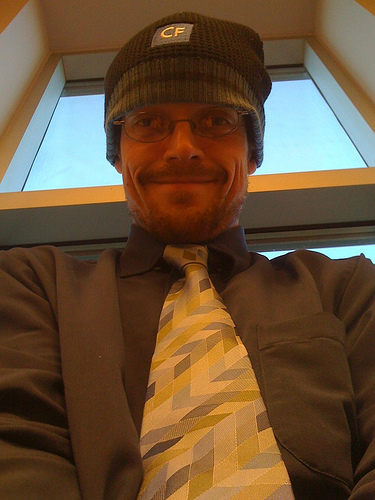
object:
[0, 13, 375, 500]
man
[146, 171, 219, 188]
mouth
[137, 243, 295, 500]
design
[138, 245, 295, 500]
tie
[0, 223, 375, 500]
shirt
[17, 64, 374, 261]
window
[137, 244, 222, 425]
road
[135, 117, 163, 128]
eye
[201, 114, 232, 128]
eye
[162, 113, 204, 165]
nose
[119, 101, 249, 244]
face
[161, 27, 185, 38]
cf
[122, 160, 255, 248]
facial hair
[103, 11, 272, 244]
head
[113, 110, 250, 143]
eye glasses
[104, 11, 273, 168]
beanie